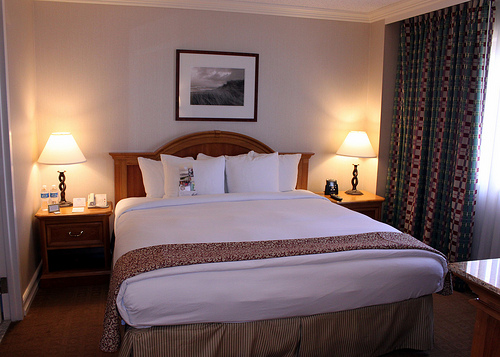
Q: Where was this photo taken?
A: In a hotel room.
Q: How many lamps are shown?
A: Two.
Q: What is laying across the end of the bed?
A: A blanket.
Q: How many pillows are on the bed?
A: Five.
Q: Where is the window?
A: To the right of the bed.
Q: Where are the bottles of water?
A: On the left nightstand.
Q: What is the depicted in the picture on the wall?
A: A landscape.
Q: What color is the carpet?
A: Brown / rust.